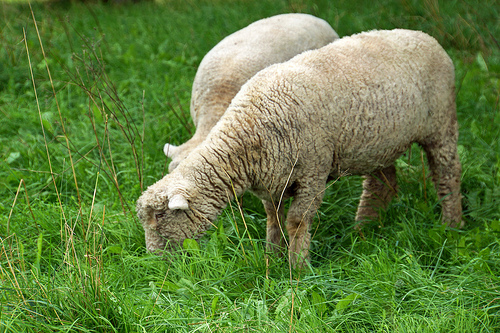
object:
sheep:
[160, 13, 339, 210]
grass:
[0, 0, 148, 233]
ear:
[163, 188, 191, 211]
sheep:
[133, 25, 464, 280]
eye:
[153, 210, 165, 220]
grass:
[287, 243, 442, 331]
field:
[2, 0, 499, 332]